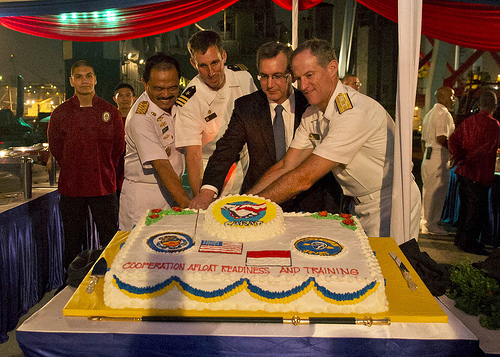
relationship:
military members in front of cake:
[49, 32, 352, 143] [103, 208, 390, 315]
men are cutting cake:
[230, 35, 292, 196] [103, 208, 390, 315]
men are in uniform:
[230, 35, 292, 196] [207, 105, 257, 165]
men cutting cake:
[230, 35, 292, 196] [103, 208, 390, 315]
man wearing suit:
[224, 20, 336, 114] [287, 194, 308, 208]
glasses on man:
[261, 74, 283, 80] [224, 20, 336, 114]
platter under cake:
[400, 296, 435, 327] [103, 208, 390, 315]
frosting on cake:
[299, 220, 316, 231] [103, 208, 390, 315]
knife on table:
[184, 203, 206, 212] [402, 321, 450, 347]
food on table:
[8, 165, 44, 192] [402, 321, 450, 347]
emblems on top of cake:
[214, 201, 276, 240] [103, 208, 390, 315]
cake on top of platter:
[103, 208, 390, 315] [400, 296, 435, 327]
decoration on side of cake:
[244, 258, 285, 282] [103, 208, 390, 315]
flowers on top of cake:
[148, 208, 167, 229] [103, 208, 390, 315]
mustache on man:
[159, 94, 174, 100] [224, 20, 336, 114]